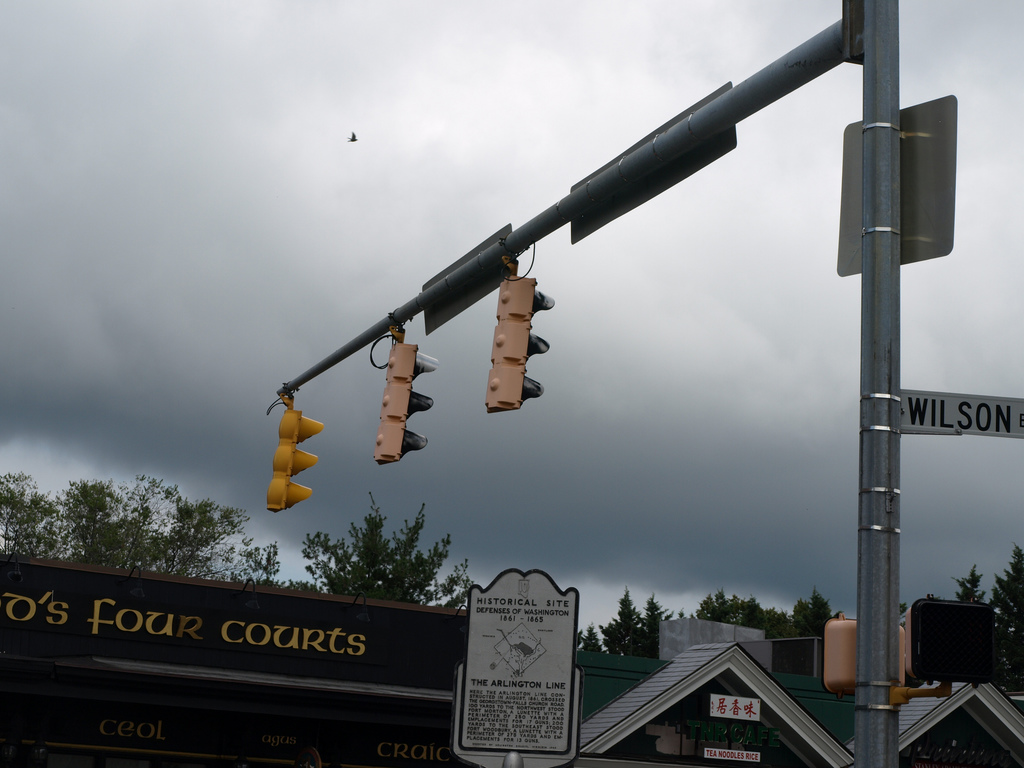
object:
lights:
[266, 392, 323, 513]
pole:
[859, 0, 900, 766]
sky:
[0, 0, 1022, 656]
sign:
[900, 388, 1024, 440]